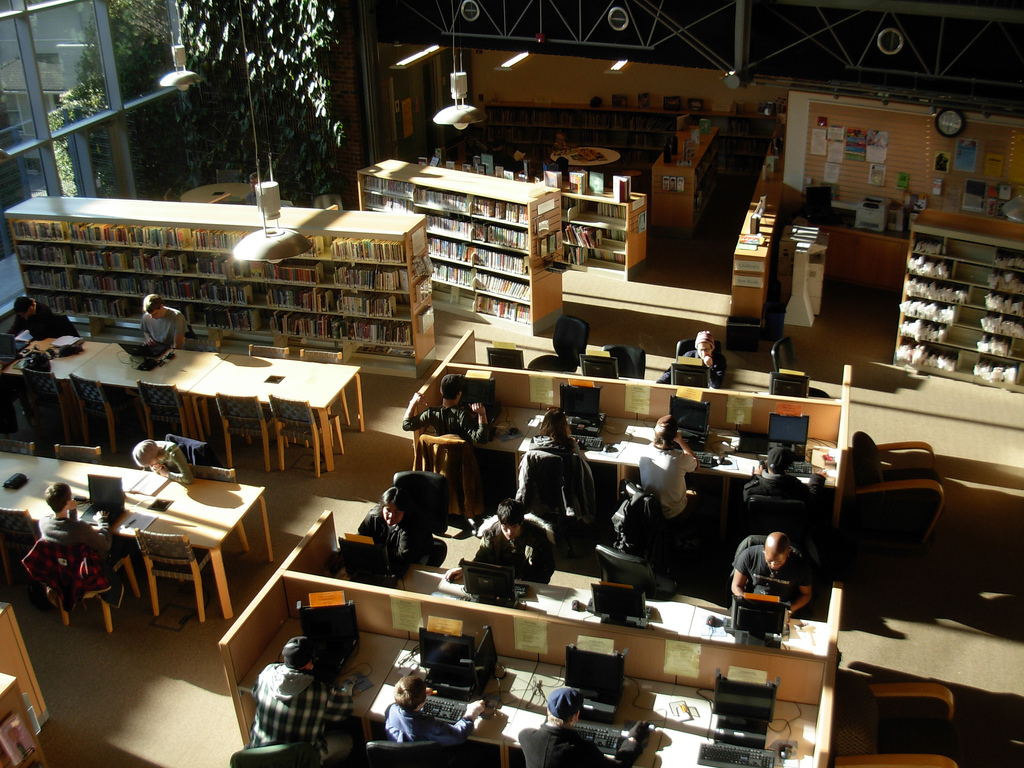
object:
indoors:
[337, 466, 681, 768]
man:
[375, 676, 479, 768]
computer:
[407, 632, 487, 724]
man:
[633, 434, 702, 509]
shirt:
[735, 552, 810, 620]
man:
[116, 292, 179, 348]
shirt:
[132, 315, 169, 342]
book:
[614, 173, 635, 203]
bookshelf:
[560, 193, 632, 227]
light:
[156, 62, 215, 94]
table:
[409, 360, 614, 473]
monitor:
[591, 572, 639, 626]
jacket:
[255, 664, 356, 746]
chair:
[140, 542, 204, 616]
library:
[28, 224, 1022, 768]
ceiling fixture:
[431, 0, 739, 89]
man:
[511, 684, 618, 764]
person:
[726, 526, 814, 617]